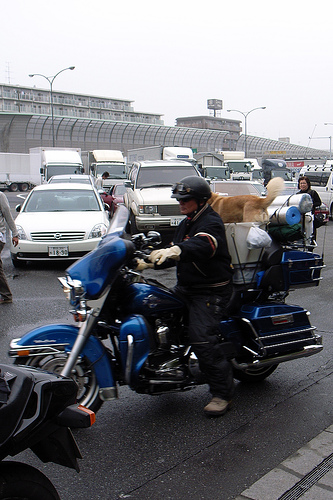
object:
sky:
[0, 0, 333, 150]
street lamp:
[68, 65, 75, 71]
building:
[0, 84, 164, 126]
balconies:
[0, 97, 165, 123]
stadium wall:
[0, 102, 333, 159]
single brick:
[240, 466, 301, 500]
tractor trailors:
[28, 145, 85, 185]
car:
[8, 183, 109, 268]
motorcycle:
[7, 200, 325, 416]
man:
[135, 173, 235, 418]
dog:
[206, 176, 285, 223]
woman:
[296, 175, 322, 253]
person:
[95, 170, 109, 188]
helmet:
[170, 175, 212, 200]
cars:
[125, 158, 202, 231]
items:
[267, 205, 302, 225]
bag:
[246, 225, 271, 249]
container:
[224, 222, 266, 264]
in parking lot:
[0, 142, 333, 499]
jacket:
[153, 203, 235, 290]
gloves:
[148, 246, 182, 265]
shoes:
[202, 393, 233, 416]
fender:
[16, 324, 115, 388]